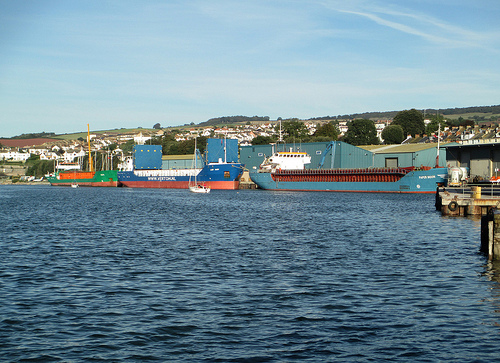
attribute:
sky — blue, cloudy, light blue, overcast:
[59, 2, 335, 90]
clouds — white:
[360, 13, 482, 58]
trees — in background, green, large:
[290, 102, 433, 150]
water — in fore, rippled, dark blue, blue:
[71, 206, 363, 326]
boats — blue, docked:
[59, 153, 443, 191]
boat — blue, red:
[260, 169, 443, 190]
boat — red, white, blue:
[113, 151, 236, 195]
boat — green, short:
[41, 166, 112, 186]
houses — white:
[24, 133, 141, 161]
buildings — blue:
[370, 141, 445, 169]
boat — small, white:
[190, 166, 216, 199]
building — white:
[5, 143, 31, 162]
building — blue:
[249, 137, 442, 170]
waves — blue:
[99, 210, 221, 315]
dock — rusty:
[440, 169, 494, 219]